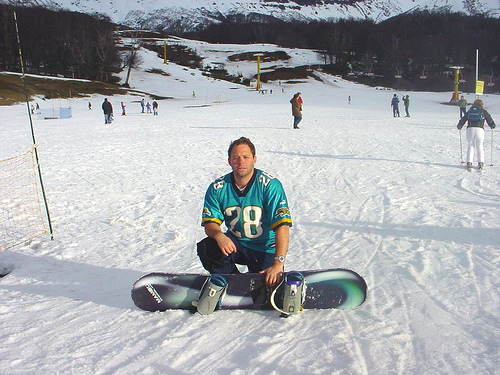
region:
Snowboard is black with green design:
[121, 265, 373, 322]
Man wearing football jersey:
[200, 170, 293, 260]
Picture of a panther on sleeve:
[268, 207, 294, 220]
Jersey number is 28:
[219, 205, 266, 242]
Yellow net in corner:
[0, 137, 45, 256]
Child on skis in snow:
[115, 99, 130, 119]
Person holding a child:
[288, 87, 306, 127]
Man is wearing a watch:
[273, 250, 287, 262]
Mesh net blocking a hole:
[30, 103, 83, 123]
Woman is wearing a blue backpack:
[460, 96, 486, 125]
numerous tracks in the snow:
[331, 174, 427, 253]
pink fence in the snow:
[12, 89, 70, 241]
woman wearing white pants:
[458, 122, 493, 166]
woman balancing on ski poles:
[454, 100, 497, 169]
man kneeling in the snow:
[194, 140, 295, 289]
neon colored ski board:
[126, 259, 372, 317]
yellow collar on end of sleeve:
[270, 211, 301, 231]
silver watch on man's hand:
[270, 251, 291, 261]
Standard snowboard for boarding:
[126, 264, 381, 314]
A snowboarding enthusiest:
[97, 108, 393, 332]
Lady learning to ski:
[439, 94, 498, 183]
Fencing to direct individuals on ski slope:
[0, 89, 97, 264]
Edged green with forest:
[0, 4, 152, 86]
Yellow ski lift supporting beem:
[252, 46, 271, 92]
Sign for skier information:
[473, 75, 493, 100]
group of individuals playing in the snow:
[56, 84, 170, 126]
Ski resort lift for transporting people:
[124, 30, 301, 106]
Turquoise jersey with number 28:
[189, 166, 322, 256]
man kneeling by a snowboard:
[131, 138, 365, 319]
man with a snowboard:
[131, 137, 364, 314]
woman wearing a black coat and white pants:
[458, 99, 497, 173]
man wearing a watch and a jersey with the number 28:
[191, 137, 296, 293]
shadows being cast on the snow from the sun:
[376, 122, 454, 247]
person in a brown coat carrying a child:
[291, 89, 308, 129]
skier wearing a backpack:
[455, 97, 497, 172]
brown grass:
[3, 72, 93, 97]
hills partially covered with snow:
[125, 27, 327, 93]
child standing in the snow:
[119, 103, 127, 115]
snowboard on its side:
[131, 268, 368, 315]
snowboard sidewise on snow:
[128, 266, 370, 318]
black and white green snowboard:
[128, 267, 370, 314]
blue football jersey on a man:
[200, 167, 294, 253]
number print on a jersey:
[222, 206, 267, 238]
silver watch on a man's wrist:
[274, 254, 286, 263]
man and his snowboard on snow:
[130, 135, 371, 317]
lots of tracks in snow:
[306, 186, 498, 374]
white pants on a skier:
[463, 127, 486, 164]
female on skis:
[455, 98, 495, 173]